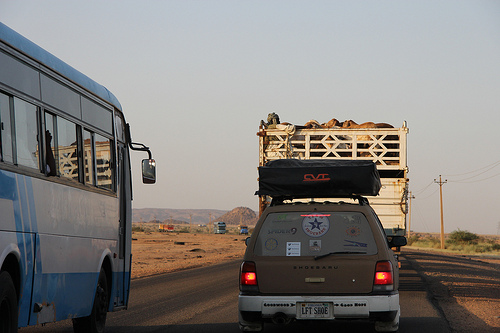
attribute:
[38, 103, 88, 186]
window — small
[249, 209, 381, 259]
car window — small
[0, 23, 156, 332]
bus — long, blue, white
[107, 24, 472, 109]
sky — blue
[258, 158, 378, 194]
bag — large, black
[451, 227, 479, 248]
bush — green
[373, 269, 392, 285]
brake lights — red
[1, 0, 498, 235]
sky — blue, clear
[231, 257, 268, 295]
tail light — red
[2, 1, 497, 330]
weather — good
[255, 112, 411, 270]
truck — big, white